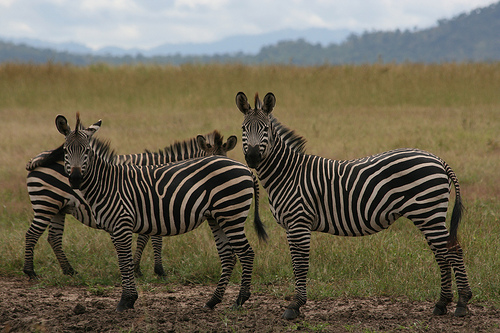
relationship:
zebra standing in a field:
[53, 114, 272, 313] [0, 60, 484, 140]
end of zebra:
[408, 140, 469, 240] [223, 81, 491, 321]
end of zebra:
[195, 140, 270, 250] [53, 114, 272, 313]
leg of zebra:
[220, 218, 265, 309] [53, 114, 272, 313]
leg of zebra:
[205, 214, 237, 308] [53, 114, 272, 313]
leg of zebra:
[444, 224, 474, 320] [231, 90, 473, 321]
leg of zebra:
[415, 224, 461, 312] [231, 90, 473, 321]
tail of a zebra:
[436, 159, 470, 245] [231, 90, 473, 321]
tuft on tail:
[246, 208, 276, 248] [247, 170, 270, 244]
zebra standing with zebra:
[231, 90, 473, 321] [53, 114, 272, 313]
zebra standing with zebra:
[53, 114, 272, 313] [13, 121, 233, 286]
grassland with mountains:
[2, 57, 498, 298] [2, 3, 498, 64]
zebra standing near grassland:
[231, 90, 473, 321] [0, 58, 499, 312]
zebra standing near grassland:
[53, 114, 272, 313] [0, 58, 499, 312]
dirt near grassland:
[4, 266, 498, 327] [0, 58, 499, 312]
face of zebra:
[241, 114, 275, 174] [224, 88, 469, 311]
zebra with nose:
[224, 88, 469, 311] [237, 146, 262, 164]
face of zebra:
[240, 114, 274, 170] [231, 90, 473, 321]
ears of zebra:
[232, 86, 279, 122] [231, 90, 473, 321]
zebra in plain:
[231, 90, 473, 321] [4, 64, 493, 331]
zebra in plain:
[53, 114, 272, 313] [4, 64, 493, 331]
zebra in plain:
[62, 119, 271, 313] [4, 64, 493, 331]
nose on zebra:
[240, 139, 272, 186] [298, 133, 481, 270]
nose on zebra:
[67, 163, 85, 195] [85, 143, 239, 296]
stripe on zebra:
[146, 169, 206, 239] [161, 157, 251, 266]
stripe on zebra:
[171, 159, 241, 237] [98, 155, 206, 264]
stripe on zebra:
[136, 173, 166, 229] [119, 175, 295, 330]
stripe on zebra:
[187, 178, 204, 224] [110, 148, 295, 297]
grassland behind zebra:
[0, 58, 499, 312] [18, 87, 421, 264]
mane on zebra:
[92, 111, 165, 163] [67, 107, 232, 322]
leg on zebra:
[205, 214, 237, 300] [53, 114, 272, 313]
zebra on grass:
[53, 114, 272, 313] [89, 267, 196, 326]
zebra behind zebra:
[53, 114, 272, 313] [231, 90, 473, 321]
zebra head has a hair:
[180, 130, 242, 161] [198, 130, 226, 146]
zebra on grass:
[7, 166, 119, 296] [45, 282, 144, 331]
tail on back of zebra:
[242, 166, 270, 240] [53, 114, 272, 313]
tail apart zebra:
[441, 161, 463, 244] [231, 90, 473, 321]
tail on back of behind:
[20, 118, 110, 168] [15, 153, 48, 216]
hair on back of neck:
[278, 118, 304, 154] [267, 122, 286, 185]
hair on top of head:
[73, 105, 82, 136] [54, 110, 101, 185]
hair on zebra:
[73, 105, 82, 136] [53, 114, 272, 313]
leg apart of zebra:
[279, 232, 311, 320] [224, 88, 469, 311]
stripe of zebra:
[347, 160, 396, 220] [231, 90, 473, 321]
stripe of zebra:
[351, 161, 431, 209] [224, 88, 469, 311]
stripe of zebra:
[171, 159, 241, 237] [53, 114, 272, 313]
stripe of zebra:
[146, 171, 167, 224] [53, 114, 272, 313]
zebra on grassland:
[53, 114, 272, 313] [0, 58, 499, 312]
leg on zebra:
[109, 232, 139, 307] [53, 114, 272, 313]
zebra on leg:
[231, 90, 473, 321] [403, 211, 458, 304]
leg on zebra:
[403, 211, 458, 304] [231, 90, 473, 321]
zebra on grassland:
[231, 90, 473, 321] [0, 58, 499, 312]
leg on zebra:
[148, 235, 163, 274] [53, 114, 272, 313]